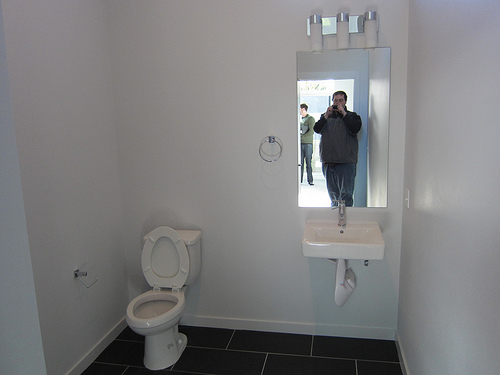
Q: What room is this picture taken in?
A: Bathroom.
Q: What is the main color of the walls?
A: White.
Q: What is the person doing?
A: Taking a picture.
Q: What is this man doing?
A: Taking a selfie.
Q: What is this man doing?
A: Taking a selfie.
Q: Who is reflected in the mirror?
A: A man taking a picture.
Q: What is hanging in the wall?
A: A mirror.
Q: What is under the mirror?
A: A white sink.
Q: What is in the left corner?
A: A white toilet.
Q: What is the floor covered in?
A: Black tile.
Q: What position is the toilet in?
A: It's up.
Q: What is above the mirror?
A: A light strip.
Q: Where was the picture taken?
A: Bathroom.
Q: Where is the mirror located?
A: Above the sink.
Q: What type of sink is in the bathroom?
A: Wall sink.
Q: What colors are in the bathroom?
A: White.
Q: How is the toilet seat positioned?
A: The seat is up.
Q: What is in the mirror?
A: Reflections of 2 people.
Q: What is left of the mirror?
A: Towel holder.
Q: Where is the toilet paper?
A: There isn't any.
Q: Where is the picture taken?
A: In a bathroom.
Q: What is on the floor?
A: Tiles.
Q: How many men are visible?
A: Two.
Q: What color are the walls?
A: White.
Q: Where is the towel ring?
A: On the wall.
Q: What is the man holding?
A: A camera.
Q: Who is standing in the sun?
A: The other man.